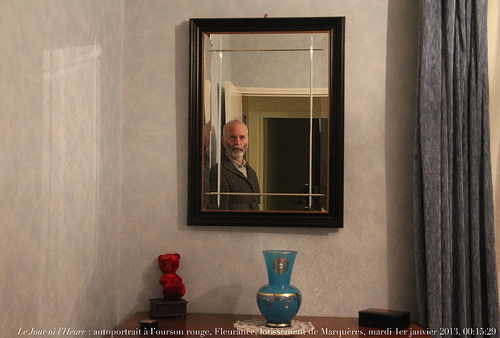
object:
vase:
[256, 249, 303, 329]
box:
[357, 307, 411, 330]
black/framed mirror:
[332, 18, 344, 225]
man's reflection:
[206, 118, 268, 209]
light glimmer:
[41, 37, 103, 327]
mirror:
[187, 18, 344, 227]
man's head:
[221, 119, 251, 159]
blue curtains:
[414, 0, 499, 336]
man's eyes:
[229, 136, 237, 139]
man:
[210, 119, 262, 212]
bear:
[158, 251, 188, 298]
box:
[147, 296, 189, 319]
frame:
[185, 16, 346, 227]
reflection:
[204, 31, 332, 211]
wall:
[0, 0, 123, 337]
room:
[0, 0, 499, 165]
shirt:
[227, 154, 249, 178]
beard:
[222, 142, 250, 159]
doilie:
[232, 317, 317, 335]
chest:
[106, 310, 434, 337]